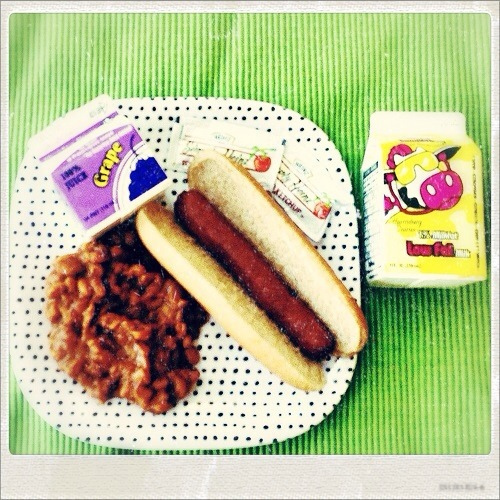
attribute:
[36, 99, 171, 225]
carton — grape juice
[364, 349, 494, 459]
plate mat — green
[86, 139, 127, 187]
yellow lettering — yellow 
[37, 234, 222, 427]
beans — brown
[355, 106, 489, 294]
carton — of milk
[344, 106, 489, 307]
carton — small 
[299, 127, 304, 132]
dot — small black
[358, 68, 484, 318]
white plate — white 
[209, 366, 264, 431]
dots — black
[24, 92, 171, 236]
juice —  carton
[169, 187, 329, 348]
hot dog — reddish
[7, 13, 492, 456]
placemat — green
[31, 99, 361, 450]
dots — black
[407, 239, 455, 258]
lettering — red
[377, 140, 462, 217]
cow — cartoon